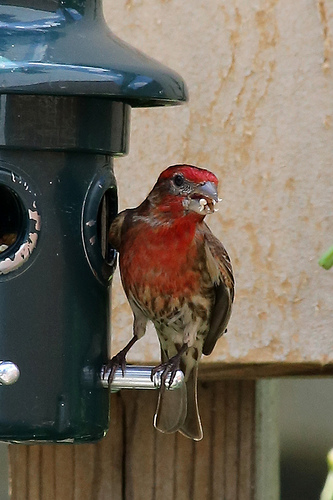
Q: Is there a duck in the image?
A: No, there are no ducks.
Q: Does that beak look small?
A: Yes, the beak is small.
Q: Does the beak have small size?
A: Yes, the beak is small.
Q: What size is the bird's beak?
A: The beak is small.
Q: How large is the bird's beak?
A: The beak is small.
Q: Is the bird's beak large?
A: No, the beak is small.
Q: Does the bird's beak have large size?
A: No, the beak is small.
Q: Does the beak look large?
A: No, the beak is small.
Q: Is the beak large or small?
A: The beak is small.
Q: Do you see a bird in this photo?
A: Yes, there is a bird.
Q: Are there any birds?
A: Yes, there is a bird.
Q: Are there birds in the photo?
A: Yes, there is a bird.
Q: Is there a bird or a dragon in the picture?
A: Yes, there is a bird.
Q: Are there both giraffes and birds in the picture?
A: No, there is a bird but no giraffes.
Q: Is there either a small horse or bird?
A: Yes, there is a small bird.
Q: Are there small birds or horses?
A: Yes, there is a small bird.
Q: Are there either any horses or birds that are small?
A: Yes, the bird is small.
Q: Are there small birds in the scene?
A: Yes, there is a small bird.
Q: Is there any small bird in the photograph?
A: Yes, there is a small bird.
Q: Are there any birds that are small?
A: Yes, there is a bird that is small.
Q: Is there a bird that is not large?
A: Yes, there is a small bird.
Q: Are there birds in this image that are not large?
A: Yes, there is a small bird.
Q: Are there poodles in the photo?
A: No, there are no poodles.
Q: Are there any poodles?
A: No, there are no poodles.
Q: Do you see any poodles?
A: No, there are no poodles.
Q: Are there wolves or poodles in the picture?
A: No, there are no poodles or wolves.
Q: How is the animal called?
A: The animal is a bird.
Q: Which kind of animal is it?
A: The animal is a bird.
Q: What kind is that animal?
A: This is a bird.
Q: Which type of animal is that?
A: This is a bird.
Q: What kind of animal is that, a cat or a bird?
A: This is a bird.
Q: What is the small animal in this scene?
A: The animal is a bird.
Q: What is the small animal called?
A: The animal is a bird.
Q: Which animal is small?
A: The animal is a bird.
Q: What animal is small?
A: The animal is a bird.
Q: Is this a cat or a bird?
A: This is a bird.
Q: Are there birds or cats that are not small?
A: No, there is a bird but it is small.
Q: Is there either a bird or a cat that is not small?
A: No, there is a bird but it is small.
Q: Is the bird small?
A: Yes, the bird is small.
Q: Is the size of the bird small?
A: Yes, the bird is small.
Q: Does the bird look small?
A: Yes, the bird is small.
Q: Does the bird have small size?
A: Yes, the bird is small.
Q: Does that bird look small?
A: Yes, the bird is small.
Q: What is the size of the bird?
A: The bird is small.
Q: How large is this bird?
A: The bird is small.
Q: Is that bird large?
A: No, the bird is small.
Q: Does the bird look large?
A: No, the bird is small.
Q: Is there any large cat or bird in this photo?
A: No, there is a bird but it is small.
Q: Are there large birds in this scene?
A: No, there is a bird but it is small.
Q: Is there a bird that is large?
A: No, there is a bird but it is small.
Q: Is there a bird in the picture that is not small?
A: No, there is a bird but it is small.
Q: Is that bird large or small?
A: The bird is small.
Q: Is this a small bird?
A: Yes, this is a small bird.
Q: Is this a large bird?
A: No, this is a small bird.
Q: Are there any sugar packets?
A: No, there are no sugar packets.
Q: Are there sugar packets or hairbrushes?
A: No, there are no sugar packets or hairbrushes.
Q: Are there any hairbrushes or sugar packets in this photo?
A: No, there are no sugar packets or hairbrushes.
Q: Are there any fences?
A: Yes, there is a fence.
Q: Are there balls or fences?
A: Yes, there is a fence.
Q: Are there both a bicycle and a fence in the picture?
A: No, there is a fence but no bicycles.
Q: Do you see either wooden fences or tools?
A: Yes, there is a wood fence.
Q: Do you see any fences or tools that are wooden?
A: Yes, the fence is wooden.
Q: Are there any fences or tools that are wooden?
A: Yes, the fence is wooden.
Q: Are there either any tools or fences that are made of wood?
A: Yes, the fence is made of wood.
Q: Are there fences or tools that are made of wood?
A: Yes, the fence is made of wood.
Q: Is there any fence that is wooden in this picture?
A: Yes, there is a wood fence.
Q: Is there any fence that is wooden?
A: Yes, there is a fence that is wooden.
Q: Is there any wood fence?
A: Yes, there is a fence that is made of wood.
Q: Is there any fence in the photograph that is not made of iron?
A: Yes, there is a fence that is made of wood.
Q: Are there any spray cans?
A: No, there are no spray cans.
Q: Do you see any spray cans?
A: No, there are no spray cans.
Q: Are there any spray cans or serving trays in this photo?
A: No, there are no spray cans or serving trays.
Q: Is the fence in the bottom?
A: Yes, the fence is in the bottom of the image.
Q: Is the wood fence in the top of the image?
A: No, the fence is in the bottom of the image.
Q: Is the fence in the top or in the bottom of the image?
A: The fence is in the bottom of the image.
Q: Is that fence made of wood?
A: Yes, the fence is made of wood.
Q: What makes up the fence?
A: The fence is made of wood.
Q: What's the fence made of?
A: The fence is made of wood.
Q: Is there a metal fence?
A: No, there is a fence but it is made of wood.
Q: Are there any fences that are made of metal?
A: No, there is a fence but it is made of wood.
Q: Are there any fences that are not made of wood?
A: No, there is a fence but it is made of wood.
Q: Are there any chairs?
A: No, there are no chairs.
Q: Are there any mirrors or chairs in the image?
A: No, there are no chairs or mirrors.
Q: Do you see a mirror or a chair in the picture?
A: No, there are no chairs or mirrors.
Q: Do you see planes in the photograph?
A: No, there are no planes.